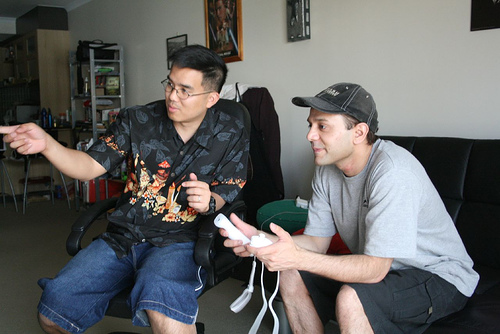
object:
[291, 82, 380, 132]
cap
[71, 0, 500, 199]
wall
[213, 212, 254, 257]
controller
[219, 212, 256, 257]
hand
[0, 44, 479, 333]
two men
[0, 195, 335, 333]
ground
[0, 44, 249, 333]
man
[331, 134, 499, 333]
couch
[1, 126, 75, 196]
table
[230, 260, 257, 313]
strap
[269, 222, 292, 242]
finger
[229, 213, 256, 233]
finger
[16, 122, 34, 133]
finger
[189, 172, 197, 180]
finger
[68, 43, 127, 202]
bookshelf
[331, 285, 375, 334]
leg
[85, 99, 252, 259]
shirt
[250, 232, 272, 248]
game controller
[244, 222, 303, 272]
hand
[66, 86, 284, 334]
chair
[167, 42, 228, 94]
hair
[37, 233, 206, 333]
jean shorts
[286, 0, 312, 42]
picture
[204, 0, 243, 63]
picture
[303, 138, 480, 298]
gray shirt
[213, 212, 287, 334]
wii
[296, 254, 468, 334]
shorts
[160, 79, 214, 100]
glasses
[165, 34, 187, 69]
picture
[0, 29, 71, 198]
bookshelf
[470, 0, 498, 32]
picture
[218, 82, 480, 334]
man